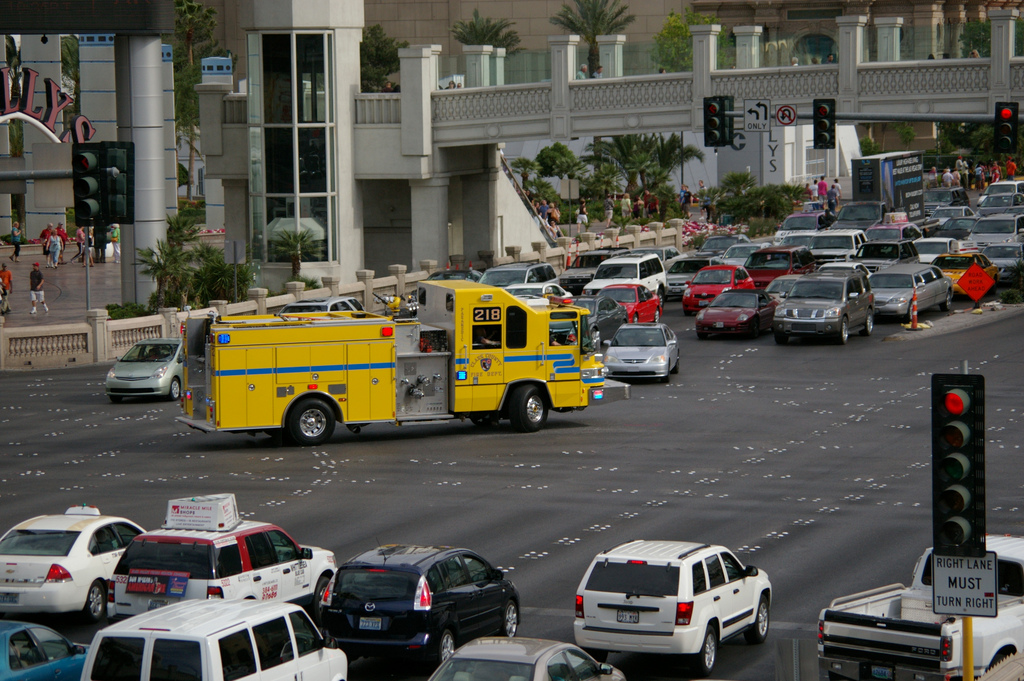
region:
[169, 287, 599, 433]
large yellow firetruck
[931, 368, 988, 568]
five light stoplight for traffic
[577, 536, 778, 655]
white sports utility vehicle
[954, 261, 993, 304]
orange sign for construction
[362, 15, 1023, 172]
Walking bridge over traffic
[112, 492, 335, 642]
white and red taxi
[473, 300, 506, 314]
Fire truck identification number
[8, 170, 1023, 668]
Vehicles stopped for a fire truck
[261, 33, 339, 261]
Windows of an elevator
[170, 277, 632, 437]
A yellow fire trucks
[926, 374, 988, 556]
The light is on red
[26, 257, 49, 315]
A man in a red hat.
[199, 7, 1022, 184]
A bridge for people to walk on.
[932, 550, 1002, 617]
A sign telling people that they must turn.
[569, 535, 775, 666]
A white car waiting to go.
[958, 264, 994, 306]
An orange construction sign.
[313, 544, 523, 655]
A black car waiting to go.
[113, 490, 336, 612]
A car with a sign on top of it.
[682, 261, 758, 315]
A red car waiting to go.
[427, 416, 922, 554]
Road is grey color.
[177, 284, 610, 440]
Truck is yellow color.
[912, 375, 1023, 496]
Red signal light is on.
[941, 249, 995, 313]
Sign board is orange and black color.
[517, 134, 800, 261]
Leaves are green color.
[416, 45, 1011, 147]
Bridge is white color.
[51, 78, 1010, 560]
Signal light is black color.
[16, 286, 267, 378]
Fence is cream color.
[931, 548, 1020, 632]
Sign board is attached to the pole.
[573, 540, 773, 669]
car stopped at red light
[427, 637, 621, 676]
car stopped at red light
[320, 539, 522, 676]
car stopped at red light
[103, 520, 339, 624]
car stopped at red light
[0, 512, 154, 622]
car stopped at red light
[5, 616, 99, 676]
car stopped at red light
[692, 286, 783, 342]
car stopped at red light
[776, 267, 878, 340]
car stopped at red light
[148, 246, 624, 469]
Fire truck on the street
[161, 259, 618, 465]
Truck on the street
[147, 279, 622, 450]
Yellow truck on the road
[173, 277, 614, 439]
Yellow truck on the street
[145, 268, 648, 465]
Fire truck on the road